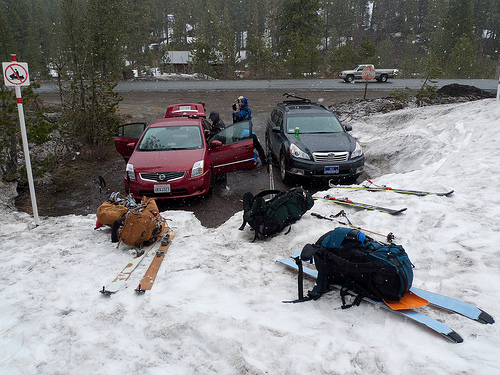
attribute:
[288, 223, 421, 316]
bag — blue, black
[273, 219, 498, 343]
skis — blue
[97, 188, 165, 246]
bag — yellow, brown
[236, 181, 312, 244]
bag — green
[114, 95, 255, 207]
vehicle — red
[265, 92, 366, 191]
vehicle — black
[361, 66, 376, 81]
sign — red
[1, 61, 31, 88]
sign — white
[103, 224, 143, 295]
skis — white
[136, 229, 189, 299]
skis — yellow, brown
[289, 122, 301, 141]
bottle — green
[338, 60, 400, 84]
car — silver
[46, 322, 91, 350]
snow — white